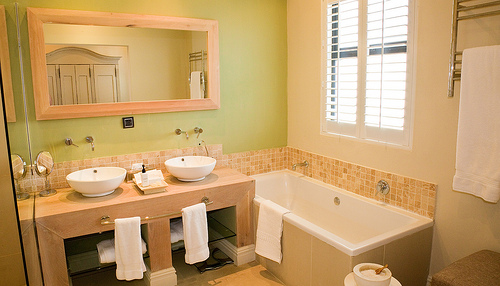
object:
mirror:
[25, 7, 222, 121]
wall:
[1, 4, 291, 154]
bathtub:
[247, 169, 435, 286]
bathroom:
[1, 0, 498, 284]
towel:
[181, 202, 210, 264]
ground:
[204, 268, 278, 286]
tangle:
[114, 216, 148, 281]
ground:
[417, 160, 431, 170]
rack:
[100, 197, 216, 226]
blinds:
[317, 0, 414, 148]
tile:
[18, 146, 438, 221]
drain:
[333, 197, 340, 206]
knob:
[375, 180, 390, 196]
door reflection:
[45, 46, 123, 106]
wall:
[215, 26, 487, 228]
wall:
[220, 3, 318, 148]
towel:
[451, 45, 499, 203]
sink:
[164, 156, 216, 182]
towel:
[254, 199, 291, 264]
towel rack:
[449, 2, 499, 99]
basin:
[66, 167, 126, 198]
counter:
[10, 163, 258, 283]